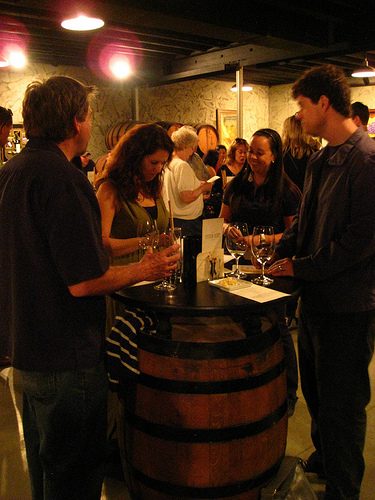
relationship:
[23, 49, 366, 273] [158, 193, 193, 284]
people drinking wine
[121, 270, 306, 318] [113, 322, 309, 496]
table made of a barrel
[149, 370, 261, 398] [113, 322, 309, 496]
rings on barrel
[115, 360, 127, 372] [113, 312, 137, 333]
black and white towel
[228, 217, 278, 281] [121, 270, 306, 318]
wine glasses on table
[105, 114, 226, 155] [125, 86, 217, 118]
barrels stacked against wall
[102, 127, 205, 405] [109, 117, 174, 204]
woman with long hair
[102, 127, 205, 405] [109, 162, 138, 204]
woman with long hair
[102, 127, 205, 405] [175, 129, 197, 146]
woman with white hair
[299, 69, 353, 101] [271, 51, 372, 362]
brown hair on a man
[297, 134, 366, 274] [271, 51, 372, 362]
shirt on a man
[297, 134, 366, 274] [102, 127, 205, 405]
shirt on a woman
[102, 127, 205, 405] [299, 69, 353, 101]
woman with brown hair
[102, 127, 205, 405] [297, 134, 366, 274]
woman with shirt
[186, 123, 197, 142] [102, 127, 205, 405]
gray hair on a woman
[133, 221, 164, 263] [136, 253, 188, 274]
wine glass in a hand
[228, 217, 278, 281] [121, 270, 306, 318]
wine glasses on a table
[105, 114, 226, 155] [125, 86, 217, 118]
barrels along wall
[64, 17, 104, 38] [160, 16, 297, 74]
lights on a ceiling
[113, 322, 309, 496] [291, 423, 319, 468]
barrel on ground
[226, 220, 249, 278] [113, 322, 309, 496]
glass on barrel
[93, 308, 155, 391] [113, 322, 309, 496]
striped shirt on barrel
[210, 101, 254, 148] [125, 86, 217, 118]
painting on wall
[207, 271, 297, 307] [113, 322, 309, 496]
menu on barrel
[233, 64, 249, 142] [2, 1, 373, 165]
support beam in room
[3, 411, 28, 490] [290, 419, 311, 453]
concrete on floor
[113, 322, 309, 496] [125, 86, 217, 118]
barrel on wall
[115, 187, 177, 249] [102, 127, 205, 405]
shirt on a woman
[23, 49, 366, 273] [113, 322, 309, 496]
people standing around barrel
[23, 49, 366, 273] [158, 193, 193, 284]
people are sipping wine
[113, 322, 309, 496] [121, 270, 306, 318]
barrel made like a table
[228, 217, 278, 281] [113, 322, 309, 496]
wine glasses on top of barrel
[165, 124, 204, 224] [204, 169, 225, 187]
people reading menu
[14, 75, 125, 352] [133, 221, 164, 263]
man holding wine glass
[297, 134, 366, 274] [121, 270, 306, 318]
shirt on table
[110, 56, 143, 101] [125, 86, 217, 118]
clock on wall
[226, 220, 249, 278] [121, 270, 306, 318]
glass on table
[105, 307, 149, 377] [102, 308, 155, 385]
striped piece of striped shirt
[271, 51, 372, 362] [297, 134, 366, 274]
man in jacket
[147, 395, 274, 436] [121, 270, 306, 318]
wooden barrel table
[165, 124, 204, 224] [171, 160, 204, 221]
people with white shirt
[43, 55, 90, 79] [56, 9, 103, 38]
overhead of lights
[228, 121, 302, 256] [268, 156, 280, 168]
woman wearing earring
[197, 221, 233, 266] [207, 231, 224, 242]
paper with words